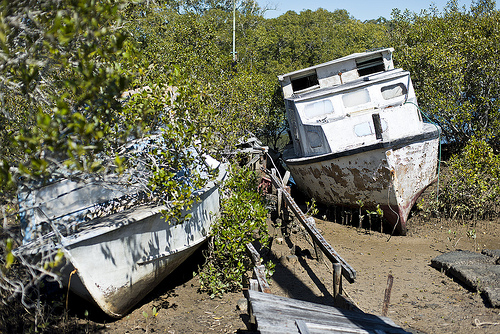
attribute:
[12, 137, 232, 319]
boat — old, white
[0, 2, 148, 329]
tree — leafy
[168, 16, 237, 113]
trees — leafy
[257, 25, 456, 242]
boat — wrecked, white